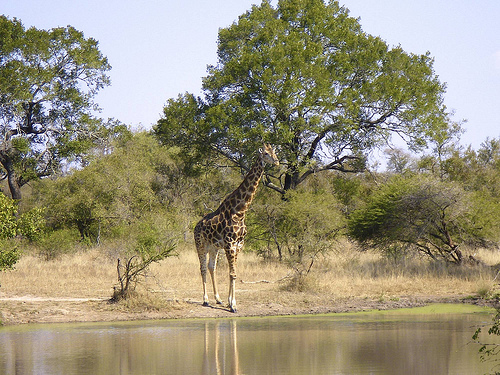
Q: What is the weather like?
A: It is clear.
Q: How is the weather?
A: It is clear.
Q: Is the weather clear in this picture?
A: Yes, it is clear.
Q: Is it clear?
A: Yes, it is clear.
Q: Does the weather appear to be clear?
A: Yes, it is clear.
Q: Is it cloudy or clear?
A: It is clear.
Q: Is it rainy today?
A: No, it is clear.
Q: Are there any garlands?
A: No, there are no garlands.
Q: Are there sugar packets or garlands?
A: No, there are no garlands or sugar packets.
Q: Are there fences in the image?
A: No, there are no fences.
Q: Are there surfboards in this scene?
A: No, there are no surfboards.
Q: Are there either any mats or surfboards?
A: No, there are no surfboards or mats.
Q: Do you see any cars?
A: No, there are no cars.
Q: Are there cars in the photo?
A: No, there are no cars.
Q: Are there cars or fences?
A: No, there are no cars or fences.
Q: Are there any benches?
A: No, there are no benches.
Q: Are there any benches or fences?
A: No, there are no benches or fences.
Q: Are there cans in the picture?
A: No, there are no cans.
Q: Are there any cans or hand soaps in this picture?
A: No, there are no cans or hand soaps.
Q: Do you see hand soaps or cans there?
A: No, there are no cans or hand soaps.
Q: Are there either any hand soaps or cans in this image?
A: No, there are no cans or hand soaps.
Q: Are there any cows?
A: No, there are no cows.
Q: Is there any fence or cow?
A: No, there are no cows or fences.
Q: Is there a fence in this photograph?
A: No, there are no fences.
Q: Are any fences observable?
A: No, there are no fences.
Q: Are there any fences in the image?
A: No, there are no fences.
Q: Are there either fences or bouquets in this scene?
A: No, there are no fences or bouquets.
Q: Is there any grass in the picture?
A: Yes, there is grass.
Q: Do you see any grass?
A: Yes, there is grass.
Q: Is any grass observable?
A: Yes, there is grass.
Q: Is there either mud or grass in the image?
A: Yes, there is grass.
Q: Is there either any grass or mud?
A: Yes, there is grass.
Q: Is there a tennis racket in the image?
A: No, there are no rackets.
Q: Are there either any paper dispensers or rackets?
A: No, there are no rackets or paper dispensers.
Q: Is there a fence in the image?
A: No, there are no fences.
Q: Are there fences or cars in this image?
A: No, there are no fences or cars.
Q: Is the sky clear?
A: Yes, the sky is clear.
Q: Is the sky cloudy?
A: No, the sky is clear.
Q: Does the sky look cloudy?
A: No, the sky is clear.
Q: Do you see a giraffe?
A: Yes, there is a giraffe.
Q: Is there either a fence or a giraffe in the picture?
A: Yes, there is a giraffe.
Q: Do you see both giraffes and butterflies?
A: No, there is a giraffe but no butterflies.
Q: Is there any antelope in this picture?
A: No, there are no antelopes.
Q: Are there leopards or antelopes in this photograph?
A: No, there are no antelopes or leopards.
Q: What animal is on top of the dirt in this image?
A: The giraffe is on top of the dirt.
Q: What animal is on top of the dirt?
A: The giraffe is on top of the dirt.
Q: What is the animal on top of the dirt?
A: The animal is a giraffe.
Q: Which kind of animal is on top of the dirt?
A: The animal is a giraffe.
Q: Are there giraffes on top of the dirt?
A: Yes, there is a giraffe on top of the dirt.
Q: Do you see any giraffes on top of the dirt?
A: Yes, there is a giraffe on top of the dirt.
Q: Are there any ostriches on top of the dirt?
A: No, there is a giraffe on top of the dirt.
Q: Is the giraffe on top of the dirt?
A: Yes, the giraffe is on top of the dirt.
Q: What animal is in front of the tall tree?
A: The giraffe is in front of the tree.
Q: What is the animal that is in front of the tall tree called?
A: The animal is a giraffe.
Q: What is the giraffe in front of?
A: The giraffe is in front of the tree.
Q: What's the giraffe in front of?
A: The giraffe is in front of the tree.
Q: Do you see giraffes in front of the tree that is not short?
A: Yes, there is a giraffe in front of the tree.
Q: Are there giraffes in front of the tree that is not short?
A: Yes, there is a giraffe in front of the tree.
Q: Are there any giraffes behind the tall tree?
A: No, the giraffe is in front of the tree.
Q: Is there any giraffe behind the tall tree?
A: No, the giraffe is in front of the tree.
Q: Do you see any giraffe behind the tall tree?
A: No, the giraffe is in front of the tree.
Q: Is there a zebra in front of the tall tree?
A: No, there is a giraffe in front of the tree.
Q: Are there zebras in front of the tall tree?
A: No, there is a giraffe in front of the tree.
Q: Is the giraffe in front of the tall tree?
A: Yes, the giraffe is in front of the tree.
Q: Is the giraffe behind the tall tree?
A: No, the giraffe is in front of the tree.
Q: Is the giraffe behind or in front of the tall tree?
A: The giraffe is in front of the tree.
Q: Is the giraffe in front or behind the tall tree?
A: The giraffe is in front of the tree.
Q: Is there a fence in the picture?
A: No, there are no fences.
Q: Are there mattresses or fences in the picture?
A: No, there are no fences or mattresses.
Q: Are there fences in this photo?
A: No, there are no fences.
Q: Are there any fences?
A: No, there are no fences.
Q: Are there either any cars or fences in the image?
A: No, there are no fences or cars.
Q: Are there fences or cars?
A: No, there are no fences or cars.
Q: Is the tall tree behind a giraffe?
A: Yes, the tree is behind a giraffe.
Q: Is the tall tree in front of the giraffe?
A: No, the tree is behind the giraffe.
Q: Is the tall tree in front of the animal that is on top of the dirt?
A: No, the tree is behind the giraffe.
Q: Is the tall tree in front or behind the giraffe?
A: The tree is behind the giraffe.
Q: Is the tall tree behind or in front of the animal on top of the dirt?
A: The tree is behind the giraffe.